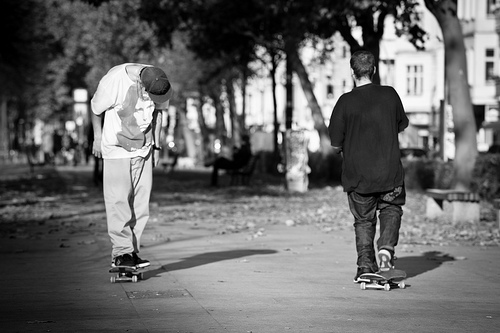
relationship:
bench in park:
[424, 187, 482, 226] [0, 145, 499, 332]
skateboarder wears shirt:
[327, 49, 412, 293] [327, 82, 412, 198]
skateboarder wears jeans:
[327, 49, 412, 293] [345, 181, 407, 271]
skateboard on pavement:
[354, 264, 410, 292] [4, 169, 500, 332]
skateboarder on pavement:
[327, 49, 412, 293] [4, 169, 500, 332]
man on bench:
[201, 132, 253, 189] [225, 153, 266, 189]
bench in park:
[225, 153, 266, 189] [0, 145, 499, 332]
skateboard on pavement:
[109, 258, 151, 285] [4, 169, 500, 332]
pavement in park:
[4, 169, 500, 332] [0, 145, 499, 332]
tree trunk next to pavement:
[423, 1, 480, 195] [4, 169, 500, 332]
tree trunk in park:
[423, 1, 480, 195] [0, 145, 499, 332]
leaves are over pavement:
[0, 179, 499, 259] [4, 169, 500, 332]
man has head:
[91, 61, 175, 267] [139, 66, 175, 106]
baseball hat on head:
[140, 66, 173, 105] [139, 66, 175, 106]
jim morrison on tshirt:
[116, 82, 157, 151] [91, 62, 172, 161]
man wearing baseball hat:
[91, 61, 175, 267] [140, 66, 173, 105]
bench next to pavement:
[225, 153, 266, 189] [4, 169, 500, 332]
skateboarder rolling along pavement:
[327, 49, 412, 293] [4, 169, 500, 332]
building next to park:
[440, 0, 496, 154] [0, 145, 499, 332]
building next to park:
[290, 8, 356, 152] [0, 145, 499, 332]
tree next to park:
[423, 0, 499, 192] [0, 145, 499, 332]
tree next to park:
[253, 8, 288, 169] [0, 145, 499, 332]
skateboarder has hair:
[327, 49, 412, 293] [349, 46, 376, 82]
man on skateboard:
[91, 61, 175, 267] [109, 258, 151, 285]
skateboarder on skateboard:
[327, 49, 412, 293] [354, 264, 410, 292]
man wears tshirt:
[91, 61, 175, 267] [91, 62, 172, 161]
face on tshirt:
[113, 83, 156, 152] [91, 62, 172, 161]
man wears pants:
[91, 61, 175, 267] [102, 148, 155, 260]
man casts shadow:
[91, 61, 175, 267] [140, 245, 281, 281]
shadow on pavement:
[140, 245, 281, 281] [4, 169, 500, 332]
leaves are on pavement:
[0, 179, 499, 259] [4, 169, 500, 332]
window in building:
[485, 47, 496, 88] [440, 0, 496, 154]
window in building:
[406, 64, 424, 100] [440, 0, 496, 154]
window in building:
[326, 73, 337, 99] [290, 8, 356, 152]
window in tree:
[260, 90, 266, 117] [423, 0, 499, 192]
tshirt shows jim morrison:
[91, 62, 172, 161] [116, 82, 157, 151]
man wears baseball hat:
[91, 61, 175, 267] [140, 66, 173, 105]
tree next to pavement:
[253, 8, 288, 169] [4, 169, 500, 332]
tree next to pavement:
[423, 0, 499, 192] [4, 169, 500, 332]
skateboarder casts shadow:
[327, 49, 412, 293] [390, 247, 460, 288]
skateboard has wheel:
[109, 258, 151, 285] [132, 275, 138, 284]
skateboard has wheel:
[109, 258, 151, 285] [108, 274, 117, 284]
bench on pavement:
[424, 187, 482, 226] [4, 169, 500, 332]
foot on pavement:
[353, 267, 375, 284] [4, 169, 500, 332]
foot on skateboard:
[111, 252, 139, 270] [109, 258, 151, 285]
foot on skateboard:
[134, 254, 151, 270] [109, 258, 151, 285]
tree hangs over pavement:
[423, 0, 499, 192] [4, 169, 500, 332]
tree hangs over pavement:
[253, 8, 288, 169] [4, 169, 500, 332]